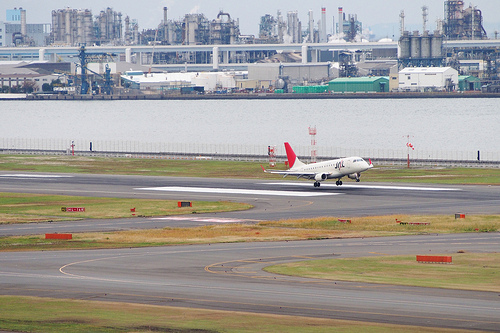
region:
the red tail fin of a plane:
[282, 142, 296, 167]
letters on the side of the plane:
[334, 161, 345, 168]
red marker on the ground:
[414, 253, 453, 265]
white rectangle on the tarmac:
[134, 181, 338, 201]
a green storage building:
[327, 74, 390, 89]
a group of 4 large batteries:
[397, 31, 446, 61]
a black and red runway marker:
[175, 199, 197, 209]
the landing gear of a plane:
[330, 174, 345, 187]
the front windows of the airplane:
[351, 158, 365, 161]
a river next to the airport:
[0, 98, 497, 161]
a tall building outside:
[47, 6, 62, 38]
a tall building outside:
[62, 5, 69, 43]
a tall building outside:
[77, 4, 85, 42]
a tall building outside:
[124, 12, 140, 48]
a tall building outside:
[158, 3, 180, 41]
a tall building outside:
[303, 1, 318, 44]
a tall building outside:
[320, 4, 331, 39]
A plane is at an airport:
[22, 109, 471, 311]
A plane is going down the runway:
[15, 111, 473, 293]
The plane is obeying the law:
[15, 105, 477, 288]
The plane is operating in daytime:
[16, 106, 472, 281]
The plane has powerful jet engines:
[32, 118, 459, 279]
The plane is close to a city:
[28, 115, 470, 290]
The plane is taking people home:
[30, 114, 468, 294]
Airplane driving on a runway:
[264, 139, 374, 187]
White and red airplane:
[257, 139, 374, 189]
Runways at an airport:
[0, 160, 499, 331]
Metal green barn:
[324, 72, 390, 93]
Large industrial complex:
[1, 3, 498, 93]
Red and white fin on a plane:
[281, 139, 306, 169]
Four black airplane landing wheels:
[310, 178, 345, 188]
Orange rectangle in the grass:
[413, 250, 454, 265]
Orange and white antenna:
[305, 122, 318, 163]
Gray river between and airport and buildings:
[1, 95, 498, 162]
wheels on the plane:
[336, 179, 342, 185]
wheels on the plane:
[315, 183, 321, 187]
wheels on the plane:
[355, 179, 362, 184]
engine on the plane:
[314, 169, 331, 179]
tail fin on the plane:
[281, 143, 300, 168]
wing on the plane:
[259, 164, 301, 176]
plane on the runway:
[263, 141, 373, 186]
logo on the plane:
[331, 162, 343, 172]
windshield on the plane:
[350, 157, 366, 166]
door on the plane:
[348, 160, 352, 167]